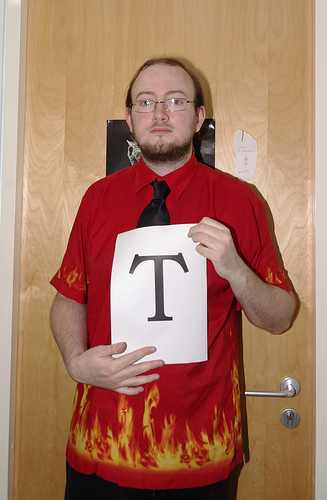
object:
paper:
[110, 223, 208, 368]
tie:
[136, 178, 170, 227]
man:
[46, 55, 301, 496]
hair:
[147, 60, 155, 64]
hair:
[150, 148, 175, 163]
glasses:
[130, 91, 197, 113]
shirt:
[49, 152, 293, 490]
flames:
[68, 361, 242, 471]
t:
[128, 252, 189, 322]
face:
[131, 63, 196, 154]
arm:
[49, 291, 88, 381]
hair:
[61, 326, 74, 344]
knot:
[152, 181, 171, 200]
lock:
[279, 408, 300, 430]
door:
[6, 0, 315, 498]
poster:
[105, 119, 215, 177]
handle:
[244, 378, 300, 399]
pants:
[65, 459, 246, 500]